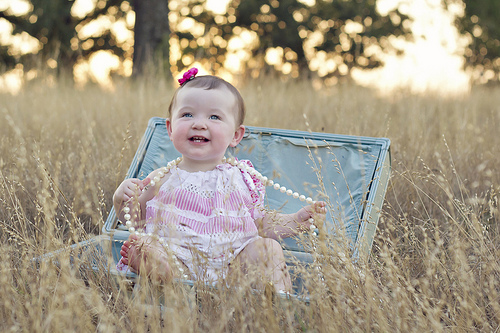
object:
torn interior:
[275, 133, 348, 150]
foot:
[114, 234, 180, 287]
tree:
[448, 4, 500, 91]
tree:
[229, 3, 406, 83]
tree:
[108, 0, 178, 88]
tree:
[0, 0, 95, 89]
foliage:
[170, 0, 430, 62]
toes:
[128, 233, 139, 243]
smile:
[179, 132, 212, 147]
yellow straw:
[0, 213, 500, 333]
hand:
[295, 200, 329, 234]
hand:
[111, 173, 162, 207]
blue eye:
[208, 113, 224, 121]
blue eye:
[180, 110, 195, 118]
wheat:
[0, 65, 500, 333]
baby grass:
[75, 65, 328, 314]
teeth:
[195, 136, 198, 139]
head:
[165, 75, 247, 160]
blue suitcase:
[26, 111, 393, 312]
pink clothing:
[137, 161, 267, 281]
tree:
[115, 0, 174, 85]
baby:
[110, 67, 327, 294]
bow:
[177, 67, 197, 86]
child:
[108, 67, 327, 307]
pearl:
[120, 146, 322, 280]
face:
[168, 86, 236, 160]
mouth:
[184, 132, 215, 145]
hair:
[164, 74, 248, 130]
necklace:
[118, 153, 324, 280]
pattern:
[145, 189, 257, 238]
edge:
[247, 127, 381, 147]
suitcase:
[21, 114, 393, 316]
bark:
[135, 6, 169, 85]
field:
[0, 80, 500, 333]